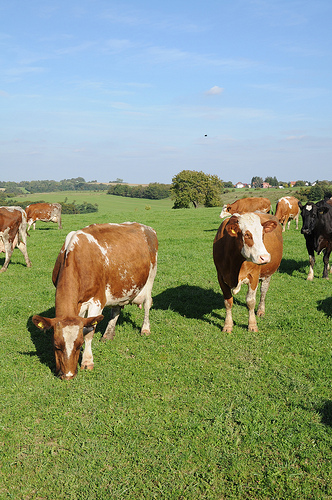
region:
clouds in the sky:
[126, 35, 201, 79]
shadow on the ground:
[312, 395, 330, 424]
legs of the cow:
[215, 290, 272, 328]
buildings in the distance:
[220, 178, 280, 205]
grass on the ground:
[150, 397, 221, 443]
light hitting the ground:
[110, 388, 227, 458]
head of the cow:
[231, 200, 294, 267]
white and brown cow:
[213, 198, 279, 276]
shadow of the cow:
[160, 282, 220, 348]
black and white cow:
[297, 201, 321, 228]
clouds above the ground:
[135, 33, 195, 80]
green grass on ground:
[105, 380, 210, 448]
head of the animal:
[23, 306, 105, 386]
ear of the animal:
[76, 308, 104, 339]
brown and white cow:
[202, 210, 281, 281]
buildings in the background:
[242, 161, 282, 191]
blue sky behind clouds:
[37, 9, 93, 44]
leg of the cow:
[129, 304, 167, 343]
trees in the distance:
[52, 179, 83, 191]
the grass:
[114, 412, 180, 490]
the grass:
[94, 384, 216, 494]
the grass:
[130, 412, 221, 498]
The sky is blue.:
[209, 22, 280, 61]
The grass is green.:
[112, 402, 211, 498]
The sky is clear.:
[226, 28, 305, 68]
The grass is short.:
[124, 373, 219, 474]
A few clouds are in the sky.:
[200, 38, 284, 120]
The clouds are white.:
[208, 52, 275, 131]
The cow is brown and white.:
[36, 215, 169, 392]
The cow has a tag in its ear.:
[21, 311, 52, 340]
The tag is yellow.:
[23, 309, 48, 337]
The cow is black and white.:
[292, 191, 331, 292]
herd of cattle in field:
[4, 191, 327, 398]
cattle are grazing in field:
[11, 200, 331, 455]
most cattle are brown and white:
[13, 197, 298, 362]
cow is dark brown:
[297, 188, 330, 262]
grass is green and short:
[17, 355, 214, 472]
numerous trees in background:
[112, 164, 219, 209]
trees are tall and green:
[166, 165, 221, 212]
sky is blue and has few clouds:
[51, 16, 186, 160]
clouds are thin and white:
[34, 50, 159, 166]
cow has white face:
[215, 212, 271, 256]